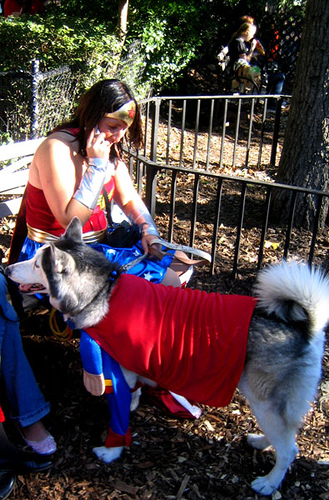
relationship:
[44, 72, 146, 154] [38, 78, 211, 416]
hair on woman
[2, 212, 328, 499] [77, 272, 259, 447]
dog in cape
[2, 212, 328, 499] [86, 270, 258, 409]
dog in cape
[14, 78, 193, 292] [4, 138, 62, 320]
costumed woman on bench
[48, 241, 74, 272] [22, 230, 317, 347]
ear of a dog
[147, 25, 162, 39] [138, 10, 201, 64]
leaves on bush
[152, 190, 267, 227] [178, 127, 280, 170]
shadow reflected by sunlight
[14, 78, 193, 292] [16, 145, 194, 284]
costumed woman wears costume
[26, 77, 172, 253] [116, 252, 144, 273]
costumed woman holds leash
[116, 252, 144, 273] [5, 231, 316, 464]
leash on dog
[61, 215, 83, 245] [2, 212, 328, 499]
ear on dog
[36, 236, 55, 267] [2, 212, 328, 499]
ear on dog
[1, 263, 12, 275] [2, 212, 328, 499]
nose on dog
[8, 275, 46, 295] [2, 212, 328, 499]
mouth on dog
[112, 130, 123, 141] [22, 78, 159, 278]
nose on woman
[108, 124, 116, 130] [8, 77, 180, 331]
eye on woman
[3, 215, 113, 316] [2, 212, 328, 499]
head on dog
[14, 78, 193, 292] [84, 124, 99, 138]
costumed woman on phone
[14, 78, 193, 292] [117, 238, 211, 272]
costumed woman holds leash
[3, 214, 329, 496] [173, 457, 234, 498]
dog on mulch